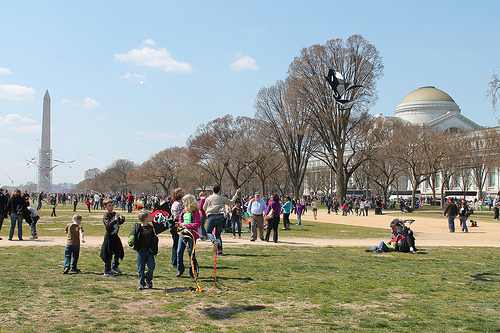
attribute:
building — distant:
[285, 85, 500, 204]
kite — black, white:
[151, 209, 177, 231]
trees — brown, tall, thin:
[78, 118, 305, 185]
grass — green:
[203, 261, 401, 328]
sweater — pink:
[176, 208, 202, 237]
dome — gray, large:
[391, 85, 456, 108]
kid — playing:
[100, 200, 124, 274]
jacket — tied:
[101, 233, 125, 262]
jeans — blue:
[103, 252, 127, 271]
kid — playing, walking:
[132, 209, 166, 286]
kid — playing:
[66, 211, 86, 268]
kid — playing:
[178, 196, 204, 276]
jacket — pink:
[174, 209, 204, 232]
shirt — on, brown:
[64, 222, 85, 245]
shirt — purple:
[266, 202, 283, 219]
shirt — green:
[248, 201, 266, 215]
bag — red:
[248, 196, 256, 206]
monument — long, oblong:
[39, 85, 54, 190]